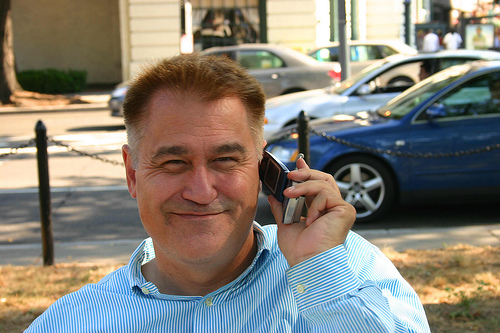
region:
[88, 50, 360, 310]
A man smiling on his cell phone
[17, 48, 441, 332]
Man on the cell phone.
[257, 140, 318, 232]
Cell phone in the hand.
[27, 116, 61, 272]
Black pole on the ground.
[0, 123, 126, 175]
Chain on the pole.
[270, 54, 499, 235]
Blue car on the street.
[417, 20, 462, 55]
People walking on the street.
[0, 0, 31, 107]
Tree trunk in the background.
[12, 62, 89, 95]
Green hedges in the background.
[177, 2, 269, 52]
Window in the building.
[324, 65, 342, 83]
Taillight on the car.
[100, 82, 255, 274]
man talking on cell phone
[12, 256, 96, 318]
grass growing on ground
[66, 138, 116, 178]
chain on metal pole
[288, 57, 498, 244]
blue car in background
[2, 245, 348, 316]
blue striped shirt on man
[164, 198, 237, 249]
smile on man's face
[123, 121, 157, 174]
gray hair around man's ears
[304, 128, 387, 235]
round black tire on car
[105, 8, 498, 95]
stores across the street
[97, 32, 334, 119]
gray car on road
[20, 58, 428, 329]
man on a cellphone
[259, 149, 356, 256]
a flip phone in the man's left hand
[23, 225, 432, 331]
blue and white striped dress shirt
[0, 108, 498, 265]
black posts with a metal chain by the road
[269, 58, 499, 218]
a blue car in the road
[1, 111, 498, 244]
the road behind the man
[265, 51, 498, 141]
white car behind the blue car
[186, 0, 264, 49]
large window on building across the street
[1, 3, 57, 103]
tree trunk and roots across the street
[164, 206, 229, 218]
the man's smile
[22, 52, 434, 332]
A man holding a phone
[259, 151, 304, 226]
A cell phone.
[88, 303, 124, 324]
Part of a striped shirt.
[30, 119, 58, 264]
A black metal pole.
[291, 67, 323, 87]
Part of a grey car.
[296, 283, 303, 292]
A small white button.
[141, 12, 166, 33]
Part of a building.